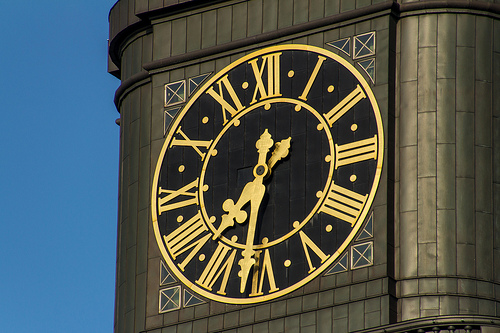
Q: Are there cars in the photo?
A: No, there are no cars.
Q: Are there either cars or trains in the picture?
A: No, there are no cars or trains.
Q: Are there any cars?
A: No, there are no cars.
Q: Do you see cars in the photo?
A: No, there are no cars.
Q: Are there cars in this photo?
A: No, there are no cars.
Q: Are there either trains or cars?
A: No, there are no cars or trains.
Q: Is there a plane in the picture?
A: No, there are no airplanes.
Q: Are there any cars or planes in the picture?
A: No, there are no planes or cars.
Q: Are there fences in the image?
A: No, there are no fences.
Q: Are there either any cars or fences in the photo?
A: No, there are no fences or cars.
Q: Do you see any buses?
A: No, there are no buses.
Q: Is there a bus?
A: No, there are no buses.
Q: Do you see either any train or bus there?
A: No, there are no buses or trains.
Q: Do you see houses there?
A: No, there are no houses.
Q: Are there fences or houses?
A: No, there are no houses or fences.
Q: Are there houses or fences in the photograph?
A: No, there are no houses or fences.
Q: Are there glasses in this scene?
A: No, there are no glasses.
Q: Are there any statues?
A: No, there are no statues.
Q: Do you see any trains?
A: No, there are no trains.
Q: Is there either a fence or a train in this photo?
A: No, there are no trains or fences.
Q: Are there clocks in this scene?
A: Yes, there is a clock.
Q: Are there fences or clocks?
A: Yes, there is a clock.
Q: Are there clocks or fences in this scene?
A: Yes, there is a clock.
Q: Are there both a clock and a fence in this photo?
A: No, there is a clock but no fences.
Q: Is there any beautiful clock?
A: Yes, there is a beautiful clock.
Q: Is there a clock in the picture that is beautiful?
A: Yes, there is a clock that is beautiful.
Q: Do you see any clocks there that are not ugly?
A: Yes, there is an beautiful clock.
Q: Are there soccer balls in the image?
A: No, there are no soccer balls.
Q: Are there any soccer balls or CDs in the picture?
A: No, there are no soccer balls or cds.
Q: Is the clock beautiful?
A: Yes, the clock is beautiful.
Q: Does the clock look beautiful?
A: Yes, the clock is beautiful.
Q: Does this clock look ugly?
A: No, the clock is beautiful.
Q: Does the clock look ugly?
A: No, the clock is beautiful.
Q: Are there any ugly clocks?
A: No, there is a clock but it is beautiful.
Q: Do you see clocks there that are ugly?
A: No, there is a clock but it is beautiful.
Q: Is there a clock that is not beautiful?
A: No, there is a clock but it is beautiful.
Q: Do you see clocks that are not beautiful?
A: No, there is a clock but it is beautiful.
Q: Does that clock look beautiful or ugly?
A: The clock is beautiful.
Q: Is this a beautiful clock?
A: Yes, this is a beautiful clock.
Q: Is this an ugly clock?
A: No, this is a beautiful clock.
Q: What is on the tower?
A: The clock is on the tower.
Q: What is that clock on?
A: The clock is on the tower.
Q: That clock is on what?
A: The clock is on the tower.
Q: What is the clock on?
A: The clock is on the tower.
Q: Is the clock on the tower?
A: Yes, the clock is on the tower.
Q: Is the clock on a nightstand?
A: No, the clock is on the tower.